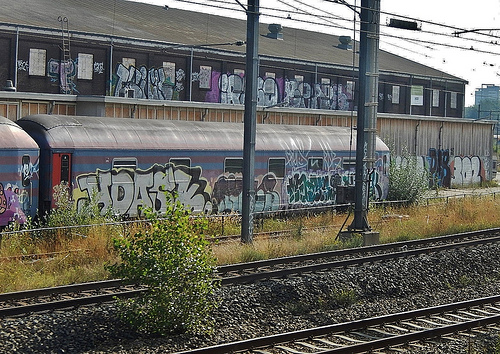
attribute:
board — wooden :
[467, 296, 499, 330]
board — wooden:
[32, 140, 74, 220]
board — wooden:
[368, 322, 403, 340]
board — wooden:
[414, 309, 444, 326]